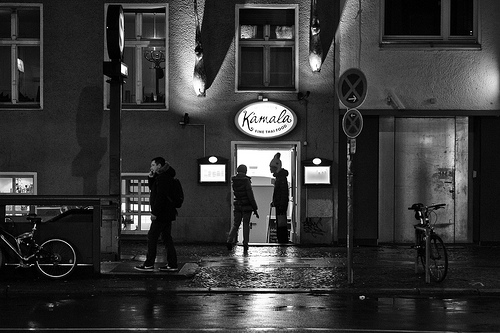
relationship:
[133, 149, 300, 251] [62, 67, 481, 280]
people by restaurant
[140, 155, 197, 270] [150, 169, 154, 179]
man on cellphone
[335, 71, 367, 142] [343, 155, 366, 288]
signs on pole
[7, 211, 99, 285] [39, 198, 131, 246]
bicycle on partition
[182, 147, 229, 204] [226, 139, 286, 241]
panels by doorway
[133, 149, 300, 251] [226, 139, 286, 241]
people by doorway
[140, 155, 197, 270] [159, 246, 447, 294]
man on sidewalk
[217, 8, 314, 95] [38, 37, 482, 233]
window on building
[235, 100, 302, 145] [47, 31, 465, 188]
sign on store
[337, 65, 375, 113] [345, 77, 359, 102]
sign has x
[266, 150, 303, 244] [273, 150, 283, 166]
person wearing cap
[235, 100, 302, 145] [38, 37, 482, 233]
sign on building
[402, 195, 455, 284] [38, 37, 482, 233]
bike by building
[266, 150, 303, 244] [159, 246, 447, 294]
person on sidewalk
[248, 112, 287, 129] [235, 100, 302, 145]
letters on sign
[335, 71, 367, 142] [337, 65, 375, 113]
signs on sign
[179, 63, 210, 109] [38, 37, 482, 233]
light on building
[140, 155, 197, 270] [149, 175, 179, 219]
man wearing jacket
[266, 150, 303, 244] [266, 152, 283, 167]
person wearing hat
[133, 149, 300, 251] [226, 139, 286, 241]
people in doorway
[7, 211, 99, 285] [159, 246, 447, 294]
bicycle on sidewalk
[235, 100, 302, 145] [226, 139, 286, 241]
sign above doorway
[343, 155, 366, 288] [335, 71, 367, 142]
pole with signs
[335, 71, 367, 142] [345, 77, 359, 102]
signs with x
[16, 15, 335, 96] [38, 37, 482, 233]
windows on building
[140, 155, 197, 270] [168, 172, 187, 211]
man wearing backpack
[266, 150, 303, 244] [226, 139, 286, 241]
person in doorway